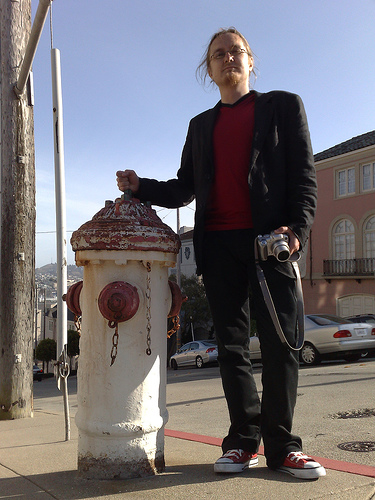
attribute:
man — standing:
[196, 34, 252, 116]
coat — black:
[161, 99, 329, 239]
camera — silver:
[246, 235, 301, 271]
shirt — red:
[213, 116, 247, 234]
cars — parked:
[172, 324, 367, 374]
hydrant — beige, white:
[63, 199, 201, 474]